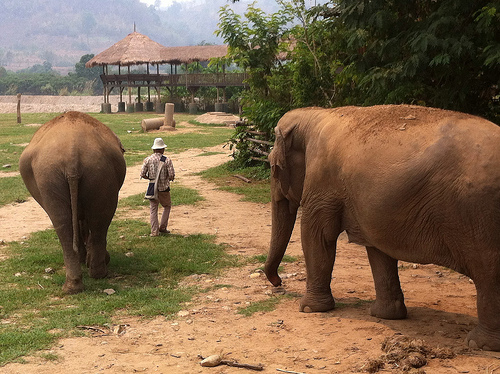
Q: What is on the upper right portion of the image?
A: Trees.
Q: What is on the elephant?
A: Dirt.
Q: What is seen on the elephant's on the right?
A: Head, ears, and trunk.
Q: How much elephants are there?
A: 2.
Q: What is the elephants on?
A: On a dirt trail.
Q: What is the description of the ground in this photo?
A: A brown dirt path.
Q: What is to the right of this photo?
A: A large brown elephant.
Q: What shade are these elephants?
A: Brown.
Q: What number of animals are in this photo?
A: Two elephants.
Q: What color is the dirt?
A: Brown.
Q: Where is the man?
A: In front of the elephants.